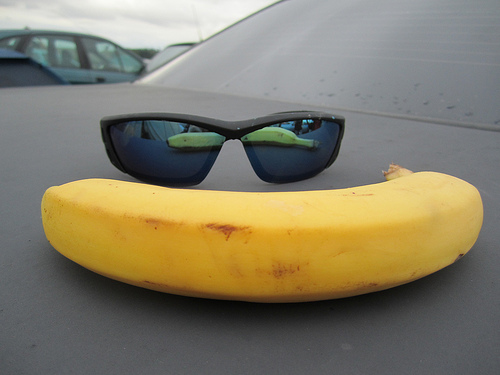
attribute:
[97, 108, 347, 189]
sunglasses — black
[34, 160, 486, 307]
banana — yellow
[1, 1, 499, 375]
car — black, gra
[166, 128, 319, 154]
reflection — banana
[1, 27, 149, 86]
car — blue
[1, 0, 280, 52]
clouds — dark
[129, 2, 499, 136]
window — dirty, black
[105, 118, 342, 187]
lenses — blue-tinted, reflective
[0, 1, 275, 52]
sky — cloudy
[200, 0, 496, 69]
lines — horizontal, white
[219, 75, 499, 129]
dots — small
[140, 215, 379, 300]
spots — brown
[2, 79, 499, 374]
car hood — black